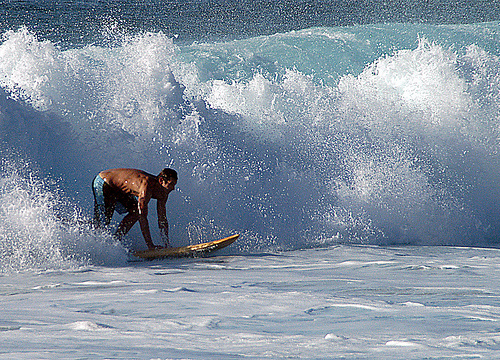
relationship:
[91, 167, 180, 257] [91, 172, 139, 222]
surfer wearing shorts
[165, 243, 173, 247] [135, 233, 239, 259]
hand on surfboard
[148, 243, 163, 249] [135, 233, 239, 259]
hand on surfboard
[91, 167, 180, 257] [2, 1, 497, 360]
surfer in ocean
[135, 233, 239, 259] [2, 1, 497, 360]
surfboard in ocean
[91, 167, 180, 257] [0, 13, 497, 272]
surfer on ocean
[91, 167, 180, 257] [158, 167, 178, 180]
surfer has hair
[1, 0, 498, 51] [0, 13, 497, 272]
water behind ocean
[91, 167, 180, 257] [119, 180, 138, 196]
surfer has ribs